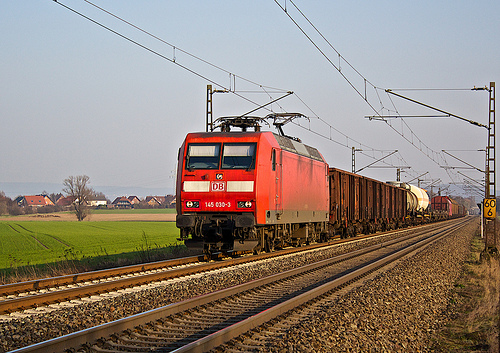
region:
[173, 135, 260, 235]
the front of a train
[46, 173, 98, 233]
a small tree in field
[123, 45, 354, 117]
lines running above train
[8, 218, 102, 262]
a worn track in a field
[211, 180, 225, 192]
Letters on a train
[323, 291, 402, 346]
gravel on side of track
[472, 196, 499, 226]
a yellow and black sign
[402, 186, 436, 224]
a white car on the train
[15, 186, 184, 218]
houses in the back ground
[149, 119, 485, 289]
a long train on the track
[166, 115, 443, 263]
Train moving down train track.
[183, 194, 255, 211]
Headlights on front of train.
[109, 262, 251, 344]
Two sets of train tracks.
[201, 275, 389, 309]
Pebbles in middle and on side of train tracks.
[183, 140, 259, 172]
Windows in front of train .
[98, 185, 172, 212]
Homes in distance from train tracks.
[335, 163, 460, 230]
Train cars train engine is pulling.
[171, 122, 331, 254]
Red train engine in front of train cars.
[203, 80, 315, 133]
Electrical connection on top of train.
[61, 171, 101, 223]
Lonely tree growing out in middle of field.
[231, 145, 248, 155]
part of a window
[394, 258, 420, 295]
part of a ground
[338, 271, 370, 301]
edge of a rail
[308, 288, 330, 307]
edge of a rail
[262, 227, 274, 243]
part of a wheel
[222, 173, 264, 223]
part of a train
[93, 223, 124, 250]
poart of a field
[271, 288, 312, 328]
edge of a rail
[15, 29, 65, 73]
white clouds in blue sky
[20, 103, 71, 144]
white clouds in blue sky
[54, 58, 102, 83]
white clouds in blue sky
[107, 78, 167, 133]
white clouds in blue sky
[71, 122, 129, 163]
white clouds in blue sky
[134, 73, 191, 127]
white clouds in blue sky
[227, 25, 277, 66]
white clouds in blue sky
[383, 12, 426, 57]
white clouds in blue sky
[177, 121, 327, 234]
train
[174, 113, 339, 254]
red train engine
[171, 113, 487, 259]
a train on rails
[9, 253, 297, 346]
two sets of railroads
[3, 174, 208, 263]
homes near a train station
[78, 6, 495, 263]
wires over the railroad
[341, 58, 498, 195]
poles holding electrical wires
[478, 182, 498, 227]
a yellow sign over electrical pole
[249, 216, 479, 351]
gravel along the railroad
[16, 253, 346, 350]
railroads are of metal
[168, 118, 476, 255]
freight train is red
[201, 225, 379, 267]
wheels of train over railroad